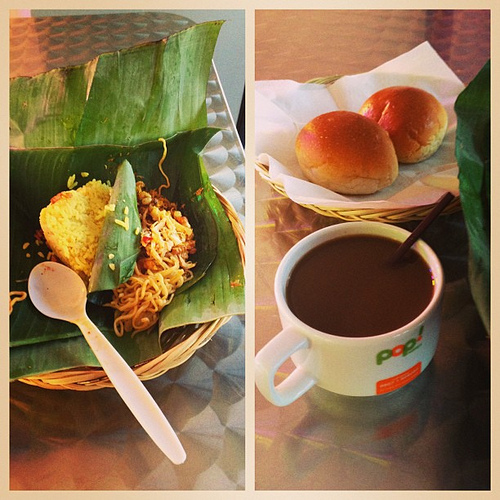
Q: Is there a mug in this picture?
A: Yes, there is a mug.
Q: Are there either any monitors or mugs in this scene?
A: Yes, there is a mug.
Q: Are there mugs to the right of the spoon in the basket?
A: Yes, there is a mug to the right of the spoon.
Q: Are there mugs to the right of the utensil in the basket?
A: Yes, there is a mug to the right of the spoon.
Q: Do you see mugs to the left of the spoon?
A: No, the mug is to the right of the spoon.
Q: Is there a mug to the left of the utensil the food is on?
A: No, the mug is to the right of the spoon.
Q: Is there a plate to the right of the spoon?
A: No, there is a mug to the right of the spoon.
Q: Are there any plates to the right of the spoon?
A: No, there is a mug to the right of the spoon.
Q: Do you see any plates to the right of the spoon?
A: No, there is a mug to the right of the spoon.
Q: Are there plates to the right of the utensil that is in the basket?
A: No, there is a mug to the right of the spoon.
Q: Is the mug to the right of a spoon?
A: Yes, the mug is to the right of a spoon.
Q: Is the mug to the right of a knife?
A: No, the mug is to the right of a spoon.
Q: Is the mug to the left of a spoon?
A: No, the mug is to the right of a spoon.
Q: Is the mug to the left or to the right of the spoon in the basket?
A: The mug is to the right of the spoon.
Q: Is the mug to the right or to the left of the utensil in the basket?
A: The mug is to the right of the spoon.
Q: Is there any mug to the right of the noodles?
A: Yes, there is a mug to the right of the noodles.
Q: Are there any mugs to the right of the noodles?
A: Yes, there is a mug to the right of the noodles.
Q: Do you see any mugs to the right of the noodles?
A: Yes, there is a mug to the right of the noodles.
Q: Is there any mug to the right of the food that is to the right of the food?
A: Yes, there is a mug to the right of the noodles.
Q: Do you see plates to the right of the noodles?
A: No, there is a mug to the right of the noodles.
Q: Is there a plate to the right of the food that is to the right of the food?
A: No, there is a mug to the right of the noodles.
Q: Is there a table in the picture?
A: Yes, there is a table.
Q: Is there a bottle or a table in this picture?
A: Yes, there is a table.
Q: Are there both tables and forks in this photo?
A: No, there is a table but no forks.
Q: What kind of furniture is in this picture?
A: The furniture is a table.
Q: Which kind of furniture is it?
A: The piece of furniture is a table.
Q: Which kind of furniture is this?
A: This is a table.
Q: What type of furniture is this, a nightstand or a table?
A: This is a table.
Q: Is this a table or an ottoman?
A: This is a table.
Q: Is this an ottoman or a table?
A: This is a table.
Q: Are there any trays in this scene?
A: No, there are no trays.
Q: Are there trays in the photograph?
A: No, there are no trays.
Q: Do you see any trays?
A: No, there are no trays.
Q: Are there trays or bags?
A: No, there are no trays or bags.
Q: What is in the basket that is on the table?
A: The buns are in the basket.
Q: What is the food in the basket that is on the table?
A: The food is buns.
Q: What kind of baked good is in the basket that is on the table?
A: The food is buns.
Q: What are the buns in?
A: The buns are in the basket.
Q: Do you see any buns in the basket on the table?
A: Yes, there are buns in the basket.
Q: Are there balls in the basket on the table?
A: No, there are buns in the basket.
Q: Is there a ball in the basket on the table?
A: No, there are buns in the basket.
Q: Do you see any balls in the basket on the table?
A: No, there are buns in the basket.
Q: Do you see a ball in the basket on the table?
A: No, there are buns in the basket.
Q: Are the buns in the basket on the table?
A: Yes, the buns are in the basket.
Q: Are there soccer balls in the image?
A: No, there are no soccer balls.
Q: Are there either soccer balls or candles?
A: No, there are no soccer balls or candles.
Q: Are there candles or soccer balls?
A: No, there are no soccer balls or candles.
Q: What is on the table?
A: The basket is on the table.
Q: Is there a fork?
A: No, there are no forks.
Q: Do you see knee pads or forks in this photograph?
A: No, there are no forks or knee pads.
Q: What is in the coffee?
A: The straw is in the coffee.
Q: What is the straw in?
A: The straw is in the coffee.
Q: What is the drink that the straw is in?
A: The drink is coffee.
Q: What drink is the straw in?
A: The straw is in the coffee.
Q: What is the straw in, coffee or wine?
A: The straw is in coffee.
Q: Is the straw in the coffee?
A: Yes, the straw is in the coffee.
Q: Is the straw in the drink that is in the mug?
A: Yes, the straw is in the coffee.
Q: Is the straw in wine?
A: No, the straw is in the coffee.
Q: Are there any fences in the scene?
A: No, there are no fences.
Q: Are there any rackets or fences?
A: No, there are no fences or rackets.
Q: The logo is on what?
A: The logo is on the mug.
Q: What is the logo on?
A: The logo is on the mug.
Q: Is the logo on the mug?
A: Yes, the logo is on the mug.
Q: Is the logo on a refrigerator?
A: No, the logo is on the mug.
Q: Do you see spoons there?
A: Yes, there is a spoon.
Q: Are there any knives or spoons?
A: Yes, there is a spoon.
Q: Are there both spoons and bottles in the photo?
A: No, there is a spoon but no bottles.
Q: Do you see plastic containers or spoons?
A: Yes, there is a plastic spoon.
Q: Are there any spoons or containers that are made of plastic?
A: Yes, the spoon is made of plastic.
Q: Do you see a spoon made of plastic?
A: Yes, there is a spoon that is made of plastic.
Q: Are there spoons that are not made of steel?
A: Yes, there is a spoon that is made of plastic.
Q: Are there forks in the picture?
A: No, there are no forks.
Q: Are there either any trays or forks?
A: No, there are no forks or trays.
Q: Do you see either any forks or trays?
A: No, there are no forks or trays.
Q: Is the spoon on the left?
A: Yes, the spoon is on the left of the image.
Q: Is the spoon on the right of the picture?
A: No, the spoon is on the left of the image.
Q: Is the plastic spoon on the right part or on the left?
A: The spoon is on the left of the image.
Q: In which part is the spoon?
A: The spoon is on the left of the image.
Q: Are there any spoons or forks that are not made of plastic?
A: No, there is a spoon but it is made of plastic.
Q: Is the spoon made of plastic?
A: Yes, the spoon is made of plastic.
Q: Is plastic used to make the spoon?
A: Yes, the spoon is made of plastic.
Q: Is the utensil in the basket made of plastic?
A: Yes, the spoon is made of plastic.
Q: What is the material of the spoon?
A: The spoon is made of plastic.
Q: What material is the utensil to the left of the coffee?
A: The spoon is made of plastic.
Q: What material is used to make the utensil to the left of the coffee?
A: The spoon is made of plastic.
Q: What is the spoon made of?
A: The spoon is made of plastic.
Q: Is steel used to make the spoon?
A: No, the spoon is made of plastic.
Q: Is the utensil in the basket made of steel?
A: No, the spoon is made of plastic.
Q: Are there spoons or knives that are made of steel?
A: No, there is a spoon but it is made of plastic.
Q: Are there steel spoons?
A: No, there is a spoon but it is made of plastic.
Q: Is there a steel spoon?
A: No, there is a spoon but it is made of plastic.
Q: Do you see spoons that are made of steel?
A: No, there is a spoon but it is made of plastic.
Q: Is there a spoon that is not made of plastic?
A: No, there is a spoon but it is made of plastic.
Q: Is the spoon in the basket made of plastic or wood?
A: The spoon is made of plastic.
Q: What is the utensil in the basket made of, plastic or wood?
A: The spoon is made of plastic.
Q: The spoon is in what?
A: The spoon is in the basket.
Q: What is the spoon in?
A: The spoon is in the basket.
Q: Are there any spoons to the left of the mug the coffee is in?
A: Yes, there is a spoon to the left of the mug.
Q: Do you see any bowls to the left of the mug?
A: No, there is a spoon to the left of the mug.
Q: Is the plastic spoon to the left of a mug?
A: Yes, the spoon is to the left of a mug.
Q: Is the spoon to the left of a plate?
A: No, the spoon is to the left of a mug.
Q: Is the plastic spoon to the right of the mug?
A: No, the spoon is to the left of the mug.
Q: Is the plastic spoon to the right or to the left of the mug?
A: The spoon is to the left of the mug.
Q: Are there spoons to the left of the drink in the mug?
A: Yes, there is a spoon to the left of the coffee.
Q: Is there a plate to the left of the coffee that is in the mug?
A: No, there is a spoon to the left of the coffee.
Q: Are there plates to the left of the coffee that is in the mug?
A: No, there is a spoon to the left of the coffee.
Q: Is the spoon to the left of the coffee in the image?
A: Yes, the spoon is to the left of the coffee.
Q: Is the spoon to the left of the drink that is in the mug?
A: Yes, the spoon is to the left of the coffee.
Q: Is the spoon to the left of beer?
A: No, the spoon is to the left of the coffee.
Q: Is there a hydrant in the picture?
A: No, there are no fire hydrants.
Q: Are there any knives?
A: No, there are no knives.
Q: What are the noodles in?
A: The noodles are in the basket.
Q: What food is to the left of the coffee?
A: The food is noodles.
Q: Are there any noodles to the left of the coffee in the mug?
A: Yes, there are noodles to the left of the coffee.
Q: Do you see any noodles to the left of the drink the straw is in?
A: Yes, there are noodles to the left of the coffee.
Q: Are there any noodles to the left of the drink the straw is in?
A: Yes, there are noodles to the left of the coffee.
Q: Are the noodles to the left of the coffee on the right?
A: Yes, the noodles are to the left of the coffee.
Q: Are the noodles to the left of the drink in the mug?
A: Yes, the noodles are to the left of the coffee.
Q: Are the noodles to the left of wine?
A: No, the noodles are to the left of the coffee.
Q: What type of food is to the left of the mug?
A: The food is noodles.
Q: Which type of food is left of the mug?
A: The food is noodles.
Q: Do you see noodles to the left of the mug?
A: Yes, there are noodles to the left of the mug.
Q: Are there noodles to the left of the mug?
A: Yes, there are noodles to the left of the mug.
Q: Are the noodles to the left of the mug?
A: Yes, the noodles are to the left of the mug.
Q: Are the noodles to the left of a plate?
A: No, the noodles are to the left of the mug.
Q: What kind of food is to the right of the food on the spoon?
A: The food is noodles.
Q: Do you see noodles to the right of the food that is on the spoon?
A: Yes, there are noodles to the right of the food.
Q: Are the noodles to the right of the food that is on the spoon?
A: Yes, the noodles are to the right of the food.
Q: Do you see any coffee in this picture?
A: Yes, there is coffee.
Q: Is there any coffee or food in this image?
A: Yes, there is coffee.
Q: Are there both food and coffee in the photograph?
A: Yes, there are both coffee and food.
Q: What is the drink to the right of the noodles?
A: The drink is coffee.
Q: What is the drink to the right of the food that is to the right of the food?
A: The drink is coffee.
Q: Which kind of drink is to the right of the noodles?
A: The drink is coffee.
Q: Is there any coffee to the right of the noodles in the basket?
A: Yes, there is coffee to the right of the noodles.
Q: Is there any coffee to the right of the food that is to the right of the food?
A: Yes, there is coffee to the right of the noodles.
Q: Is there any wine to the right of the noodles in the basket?
A: No, there is coffee to the right of the noodles.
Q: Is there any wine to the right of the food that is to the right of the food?
A: No, there is coffee to the right of the noodles.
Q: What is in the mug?
A: The coffee is in the mug.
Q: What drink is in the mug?
A: The drink is coffee.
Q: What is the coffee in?
A: The coffee is in the mug.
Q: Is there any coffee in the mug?
A: Yes, there is coffee in the mug.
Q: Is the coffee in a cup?
A: No, the coffee is in the mug.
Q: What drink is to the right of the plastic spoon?
A: The drink is coffee.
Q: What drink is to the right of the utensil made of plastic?
A: The drink is coffee.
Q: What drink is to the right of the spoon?
A: The drink is coffee.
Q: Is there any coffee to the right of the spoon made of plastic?
A: Yes, there is coffee to the right of the spoon.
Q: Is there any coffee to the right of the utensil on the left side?
A: Yes, there is coffee to the right of the spoon.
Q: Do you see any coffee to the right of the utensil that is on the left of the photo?
A: Yes, there is coffee to the right of the spoon.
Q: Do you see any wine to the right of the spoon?
A: No, there is coffee to the right of the spoon.